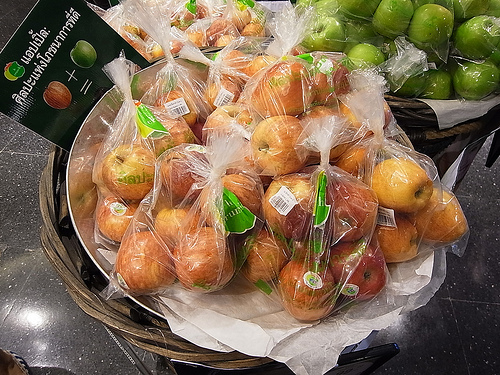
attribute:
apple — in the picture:
[307, 0, 499, 100]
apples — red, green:
[287, 2, 498, 99]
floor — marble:
[2, 108, 496, 371]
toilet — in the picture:
[405, 2, 460, 54]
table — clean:
[2, 2, 497, 372]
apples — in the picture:
[107, 62, 407, 279]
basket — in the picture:
[37, 43, 412, 370]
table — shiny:
[0, 142, 37, 357]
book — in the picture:
[2, 0, 129, 127]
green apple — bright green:
[453, 11, 498, 58]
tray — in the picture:
[63, 45, 408, 323]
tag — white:
[269, 191, 300, 216]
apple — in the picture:
[426, 69, 453, 101]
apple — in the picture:
[343, 40, 389, 73]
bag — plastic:
[263, 128, 388, 327]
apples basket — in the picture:
[38, 46, 467, 373]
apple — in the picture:
[243, 100, 316, 192]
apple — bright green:
[405, 3, 452, 51]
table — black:
[4, 136, 37, 349]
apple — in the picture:
[369, 12, 425, 39]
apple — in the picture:
[454, 55, 498, 100]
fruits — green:
[132, 131, 395, 288]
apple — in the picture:
[404, 187, 467, 242]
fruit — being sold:
[89, 3, 499, 325]